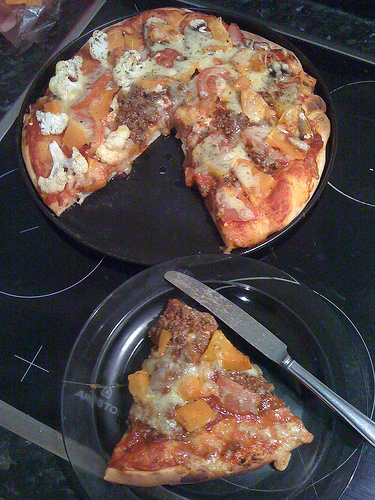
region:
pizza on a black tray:
[37, 21, 312, 216]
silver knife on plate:
[166, 271, 360, 387]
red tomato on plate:
[214, 376, 254, 413]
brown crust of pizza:
[141, 457, 180, 492]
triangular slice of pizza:
[119, 304, 254, 463]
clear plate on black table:
[60, 309, 133, 416]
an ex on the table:
[4, 339, 52, 401]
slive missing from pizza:
[118, 113, 202, 213]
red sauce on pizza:
[260, 168, 296, 232]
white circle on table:
[1, 160, 68, 331]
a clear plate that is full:
[55, 254, 371, 498]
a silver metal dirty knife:
[162, 271, 373, 440]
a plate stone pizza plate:
[22, 9, 332, 261]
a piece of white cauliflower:
[41, 139, 87, 186]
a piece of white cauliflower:
[35, 106, 70, 133]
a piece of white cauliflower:
[93, 122, 130, 156]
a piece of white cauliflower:
[91, 29, 111, 61]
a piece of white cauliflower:
[50, 59, 92, 97]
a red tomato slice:
[216, 379, 257, 412]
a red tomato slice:
[219, 185, 256, 218]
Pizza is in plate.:
[28, 36, 310, 212]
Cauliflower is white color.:
[40, 113, 82, 184]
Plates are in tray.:
[26, 210, 161, 375]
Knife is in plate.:
[165, 255, 337, 411]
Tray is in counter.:
[293, 7, 363, 83]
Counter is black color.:
[273, 2, 363, 38]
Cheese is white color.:
[195, 126, 242, 163]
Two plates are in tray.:
[80, 145, 283, 377]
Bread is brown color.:
[276, 173, 307, 216]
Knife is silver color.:
[228, 308, 341, 431]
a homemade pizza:
[11, 34, 347, 260]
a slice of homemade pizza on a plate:
[86, 324, 358, 489]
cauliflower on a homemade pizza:
[37, 142, 106, 195]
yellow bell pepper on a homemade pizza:
[168, 395, 236, 443]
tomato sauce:
[118, 437, 162, 468]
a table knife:
[169, 258, 372, 390]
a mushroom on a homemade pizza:
[180, 20, 213, 36]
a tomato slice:
[219, 357, 270, 411]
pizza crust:
[86, 439, 332, 489]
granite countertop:
[5, 450, 58, 489]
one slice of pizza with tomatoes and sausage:
[106, 306, 305, 472]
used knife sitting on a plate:
[160, 262, 369, 437]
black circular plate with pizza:
[68, 257, 363, 494]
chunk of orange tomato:
[174, 397, 213, 427]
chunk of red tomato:
[214, 376, 259, 415]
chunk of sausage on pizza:
[156, 304, 212, 361]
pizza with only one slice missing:
[28, 12, 331, 261]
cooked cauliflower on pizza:
[38, 142, 95, 187]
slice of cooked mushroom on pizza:
[176, 16, 215, 50]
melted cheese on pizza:
[193, 133, 248, 178]